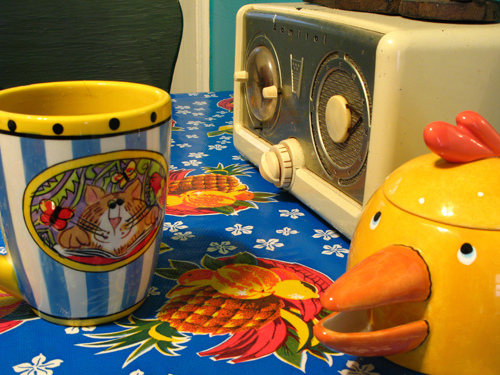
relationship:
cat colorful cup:
[63, 181, 160, 253] [2, 70, 177, 332]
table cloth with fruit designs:
[173, 90, 230, 372] [169, 162, 275, 220]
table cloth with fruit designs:
[173, 90, 230, 372] [80, 251, 351, 373]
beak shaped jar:
[318, 247, 428, 357] [307, 108, 497, 373]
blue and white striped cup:
[46, 263, 68, 315] [2, 70, 177, 332]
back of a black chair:
[125, 50, 158, 75] [1, 0, 183, 98]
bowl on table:
[278, 235, 408, 333] [38, 301, 294, 375]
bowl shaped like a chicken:
[278, 115, 498, 333] [310, 214, 491, 361]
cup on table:
[2, 70, 177, 332] [0, 86, 469, 372]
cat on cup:
[24, 40, 209, 295] [0, 48, 205, 350]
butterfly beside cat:
[37, 199, 73, 230] [63, 181, 160, 253]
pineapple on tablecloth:
[179, 269, 295, 349] [77, 132, 364, 367]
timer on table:
[223, 4, 438, 231] [86, 259, 297, 355]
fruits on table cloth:
[154, 288, 282, 332] [197, 181, 292, 345]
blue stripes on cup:
[84, 258, 120, 308] [12, 73, 175, 371]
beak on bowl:
[318, 247, 428, 357] [278, 115, 498, 333]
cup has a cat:
[2, 70, 177, 332] [60, 183, 162, 253]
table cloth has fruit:
[173, 90, 257, 371] [73, 247, 335, 369]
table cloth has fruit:
[173, 90, 257, 371] [168, 160, 270, 222]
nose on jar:
[308, 240, 433, 359] [307, 108, 497, 373]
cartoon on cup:
[27, 152, 170, 260] [35, 74, 215, 306]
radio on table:
[214, 4, 500, 191] [145, 89, 254, 240]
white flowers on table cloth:
[220, 218, 296, 252] [181, 191, 244, 255]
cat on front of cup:
[63, 181, 160, 253] [2, 70, 177, 332]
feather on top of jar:
[421, 109, 498, 166] [307, 108, 497, 373]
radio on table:
[235, 4, 499, 225] [3, 83, 414, 371]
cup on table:
[2, 70, 177, 332] [1, 85, 356, 372]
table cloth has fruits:
[173, 90, 257, 371] [176, 255, 313, 367]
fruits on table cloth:
[176, 255, 313, 367] [173, 90, 257, 371]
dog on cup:
[62, 182, 153, 259] [2, 70, 177, 332]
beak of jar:
[310, 242, 432, 357] [307, 108, 497, 373]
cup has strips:
[2, 70, 177, 332] [3, 138, 71, 162]